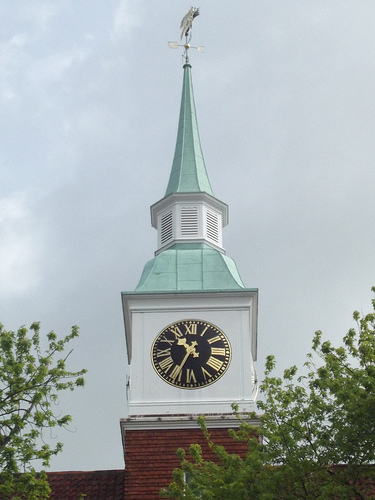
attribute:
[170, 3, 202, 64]
weather vane — silver, directional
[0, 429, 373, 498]
brick — red, wall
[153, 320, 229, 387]
clock — black, gold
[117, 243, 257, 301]
roof — light blue-green, green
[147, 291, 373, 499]
tree — leafy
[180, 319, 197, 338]
roman numerals — gold, encircled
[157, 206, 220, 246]
air vents — white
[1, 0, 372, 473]
sky — soft blue, cloudy, blue gray, very cloudy, whit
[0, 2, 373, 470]
clouds — white, here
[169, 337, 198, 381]
hands — gold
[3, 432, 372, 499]
building — here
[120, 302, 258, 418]
wall — white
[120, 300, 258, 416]
steeple — white, green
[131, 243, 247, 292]
shingles — green, dome shaped